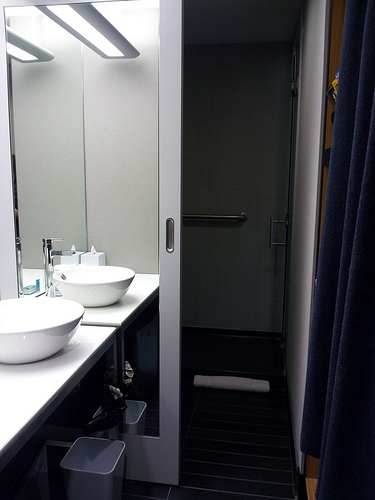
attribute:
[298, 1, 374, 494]
curtain — long and dark blue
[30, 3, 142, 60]
light — long rectangular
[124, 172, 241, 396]
mirror — very tall